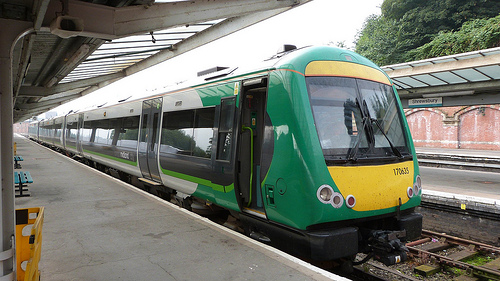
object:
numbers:
[396, 168, 399, 175]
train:
[26, 43, 427, 261]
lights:
[316, 184, 334, 204]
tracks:
[441, 246, 484, 274]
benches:
[13, 155, 23, 169]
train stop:
[14, 130, 304, 277]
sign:
[407, 97, 443, 108]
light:
[54, 41, 93, 78]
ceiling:
[12, 0, 312, 124]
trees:
[334, 0, 500, 68]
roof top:
[379, 46, 500, 88]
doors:
[135, 96, 164, 185]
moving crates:
[14, 206, 49, 280]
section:
[330, 162, 411, 209]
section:
[263, 72, 334, 237]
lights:
[345, 194, 356, 208]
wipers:
[345, 98, 372, 162]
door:
[235, 78, 270, 220]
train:
[29, 52, 424, 247]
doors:
[76, 111, 86, 158]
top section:
[30, 56, 310, 107]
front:
[305, 205, 431, 270]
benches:
[14, 171, 34, 199]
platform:
[11, 131, 343, 278]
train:
[26, 44, 424, 273]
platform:
[13, 147, 263, 274]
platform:
[412, 152, 499, 198]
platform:
[420, 155, 494, 215]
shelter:
[1, 0, 317, 277]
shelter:
[379, 40, 500, 109]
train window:
[158, 105, 218, 160]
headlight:
[330, 192, 344, 208]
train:
[48, 70, 453, 252]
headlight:
[407, 187, 414, 199]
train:
[64, 44, 461, 269]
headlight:
[414, 184, 419, 195]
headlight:
[416, 175, 423, 189]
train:
[20, 52, 387, 269]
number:
[393, 168, 397, 175]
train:
[43, 39, 442, 264]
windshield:
[303, 75, 414, 167]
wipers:
[362, 97, 404, 159]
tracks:
[366, 224, 454, 252]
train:
[66, 21, 455, 278]